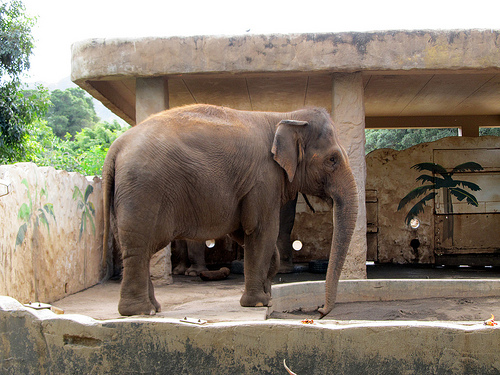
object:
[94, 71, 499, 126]
ceiling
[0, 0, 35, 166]
tree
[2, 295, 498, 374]
wall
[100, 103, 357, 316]
elephant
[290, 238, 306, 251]
hole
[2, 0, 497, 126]
sky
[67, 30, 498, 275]
shelter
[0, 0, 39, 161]
tree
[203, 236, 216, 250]
hole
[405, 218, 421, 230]
hole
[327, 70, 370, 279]
column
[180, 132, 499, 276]
wall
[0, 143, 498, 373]
enclosure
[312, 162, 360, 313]
trunk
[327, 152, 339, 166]
eye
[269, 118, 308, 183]
ear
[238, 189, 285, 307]
leg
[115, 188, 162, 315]
leg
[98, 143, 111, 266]
tail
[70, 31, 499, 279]
structure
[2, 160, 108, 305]
wall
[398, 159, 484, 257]
tree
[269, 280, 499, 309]
concrete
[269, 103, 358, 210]
head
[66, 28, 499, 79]
roof